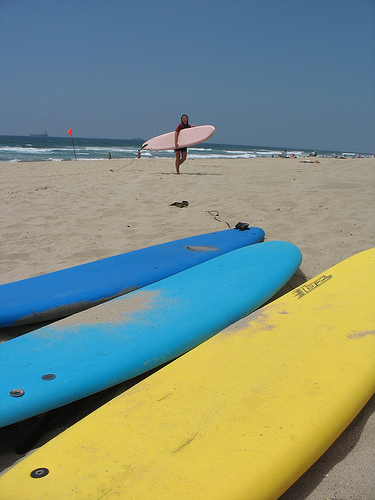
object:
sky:
[0, 0, 375, 155]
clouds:
[0, 0, 375, 156]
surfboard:
[142, 125, 215, 150]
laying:
[0, 227, 374, 500]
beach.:
[0, 155, 373, 500]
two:
[0, 222, 304, 432]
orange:
[67, 128, 72, 137]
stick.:
[72, 138, 76, 161]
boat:
[30, 131, 48, 137]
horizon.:
[0, 135, 374, 161]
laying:
[299, 160, 320, 163]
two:
[107, 149, 141, 159]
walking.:
[137, 150, 141, 158]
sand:
[0, 155, 373, 498]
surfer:
[175, 114, 195, 173]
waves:
[0, 144, 374, 164]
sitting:
[358, 153, 361, 158]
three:
[2, 222, 375, 500]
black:
[136, 143, 148, 156]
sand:
[48, 291, 176, 331]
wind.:
[1, 1, 374, 162]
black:
[174, 114, 188, 151]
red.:
[176, 123, 191, 132]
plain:
[0, 243, 374, 500]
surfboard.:
[1, 246, 374, 498]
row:
[1, 226, 374, 499]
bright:
[1, 226, 264, 327]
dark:
[0, 227, 266, 325]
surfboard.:
[0, 221, 266, 332]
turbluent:
[1, 133, 374, 164]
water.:
[1, 135, 374, 161]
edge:
[0, 156, 375, 162]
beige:
[2, 155, 373, 500]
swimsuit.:
[175, 121, 192, 152]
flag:
[67, 128, 76, 160]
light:
[0, 224, 265, 329]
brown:
[1, 154, 374, 499]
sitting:
[307, 151, 317, 157]